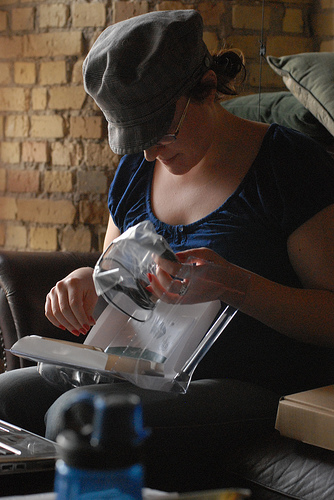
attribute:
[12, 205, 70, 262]
brick — brown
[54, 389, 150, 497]
bottle — water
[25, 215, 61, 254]
brick — brown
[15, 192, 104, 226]
brick — brown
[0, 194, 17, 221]
brick — brown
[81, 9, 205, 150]
cap — blue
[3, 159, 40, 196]
brick — brown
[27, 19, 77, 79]
wall — brick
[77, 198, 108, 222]
brick — brown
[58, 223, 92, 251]
brick — brown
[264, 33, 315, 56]
brick — brown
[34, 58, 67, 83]
brick — brown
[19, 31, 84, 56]
brick — brown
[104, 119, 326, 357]
blouse — blue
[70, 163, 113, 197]
brick — brown